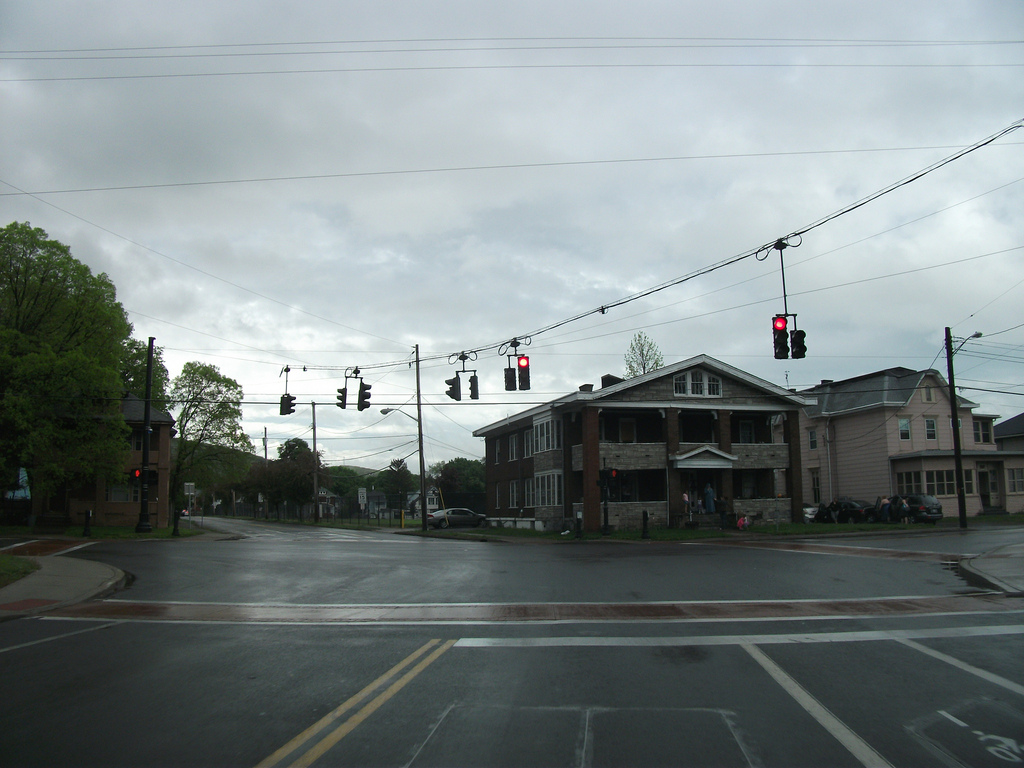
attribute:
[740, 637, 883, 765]
line — white 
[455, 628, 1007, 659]
line — white 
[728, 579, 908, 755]
line — white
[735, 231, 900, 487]
light — red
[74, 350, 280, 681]
sign — distant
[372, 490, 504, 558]
car — parked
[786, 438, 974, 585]
van — parked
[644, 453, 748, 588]
porch — brown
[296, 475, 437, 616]
sign — white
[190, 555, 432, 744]
line — yellow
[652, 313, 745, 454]
window — small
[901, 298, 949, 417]
window — small